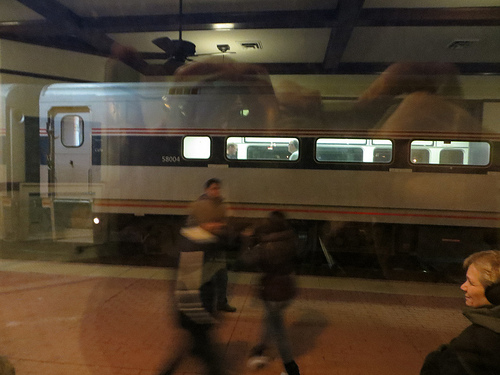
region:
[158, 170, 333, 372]
People in the foreground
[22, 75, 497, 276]
A train in the background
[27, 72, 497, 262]
A side view of a train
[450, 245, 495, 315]
A side view of a person's head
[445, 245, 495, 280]
Person has blonde colored hair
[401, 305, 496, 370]
Person is wearing a coat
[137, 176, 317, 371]
People in the foreground are blurred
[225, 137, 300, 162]
Two people inside the train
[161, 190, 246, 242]
Person is wearing a tan colored cap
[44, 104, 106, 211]
A train door is in full view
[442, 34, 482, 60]
vent in the white ceiling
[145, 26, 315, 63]
vent in white square of ceiling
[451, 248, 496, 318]
woman with blond hair and black earmuffs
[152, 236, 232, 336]
reflection of a cell phone in glass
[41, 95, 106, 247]
doorway entrance of a train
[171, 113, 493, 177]
lighted windows of a train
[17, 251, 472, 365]
red and white platform next to train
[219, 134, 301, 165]
two people sitting on a train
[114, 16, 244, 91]
ceiling fan in a train station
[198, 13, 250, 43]
light in the ceiling of a train station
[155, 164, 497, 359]
four people on train platform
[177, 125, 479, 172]
windows on side of train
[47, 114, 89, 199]
gray door of train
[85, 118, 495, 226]
red stripes on side of train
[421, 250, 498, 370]
lady wearing black ear muffs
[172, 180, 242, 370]
man wearing blue and white jacket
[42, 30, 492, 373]
reflection on train window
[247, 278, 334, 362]
shadow on train platform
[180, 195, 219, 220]
hat of man in blue and white coat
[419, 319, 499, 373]
black coat of woman wearing ear muffs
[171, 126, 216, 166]
Small window on train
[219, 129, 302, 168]
Small window on train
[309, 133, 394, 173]
Small window on train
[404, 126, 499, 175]
Small window on train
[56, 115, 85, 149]
Small window on train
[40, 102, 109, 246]
Silver door on a train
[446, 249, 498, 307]
Woman wearing black ear muffs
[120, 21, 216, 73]
Small black ceiling fan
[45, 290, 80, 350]
Red brick pavement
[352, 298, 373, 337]
Section of red brick pavement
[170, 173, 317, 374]
People walking at the train station.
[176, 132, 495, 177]
Windows on the train.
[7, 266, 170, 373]
Red brick on the sidewalk.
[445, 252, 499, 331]
Woman wearing black ear muffs.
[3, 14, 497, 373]
Glass window pane at train station.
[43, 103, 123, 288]
Door on the side of the train.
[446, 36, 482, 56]
White vent in the ceiling.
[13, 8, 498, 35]
Brown beams on the ceiling.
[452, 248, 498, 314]
Blond hair on the woman.